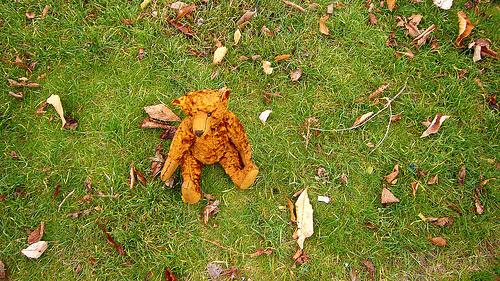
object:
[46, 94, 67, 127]
leaf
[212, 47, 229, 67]
leaf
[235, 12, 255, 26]
leaf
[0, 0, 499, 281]
grass